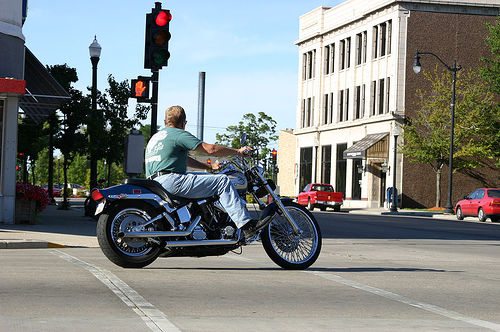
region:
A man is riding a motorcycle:
[30, 22, 485, 317]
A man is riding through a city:
[17, 36, 472, 308]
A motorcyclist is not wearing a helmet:
[25, 40, 455, 305]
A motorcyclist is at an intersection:
[21, 50, 481, 315]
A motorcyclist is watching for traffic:
[20, 26, 463, 322]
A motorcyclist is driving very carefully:
[2, 48, 474, 314]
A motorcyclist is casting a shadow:
[15, 25, 480, 316]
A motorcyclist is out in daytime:
[31, 16, 471, 321]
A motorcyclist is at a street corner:
[11, 51, 452, 328]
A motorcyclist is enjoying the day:
[40, 28, 447, 298]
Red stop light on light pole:
[138, 7, 183, 73]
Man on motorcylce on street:
[68, 105, 341, 270]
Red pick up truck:
[293, 178, 347, 210]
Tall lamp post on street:
[396, 42, 470, 209]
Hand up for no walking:
[123, 78, 150, 102]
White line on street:
[62, 266, 174, 330]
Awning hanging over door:
[336, 130, 397, 161]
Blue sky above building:
[215, 43, 288, 87]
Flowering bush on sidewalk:
[16, 178, 51, 225]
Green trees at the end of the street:
[236, 107, 273, 143]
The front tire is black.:
[265, 196, 321, 270]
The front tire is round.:
[258, 203, 323, 268]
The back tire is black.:
[96, 198, 168, 266]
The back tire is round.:
[96, 194, 167, 270]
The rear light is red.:
[91, 185, 102, 202]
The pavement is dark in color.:
[232, 277, 307, 320]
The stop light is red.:
[153, 6, 173, 30]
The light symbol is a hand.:
[131, 81, 152, 98]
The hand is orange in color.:
[132, 75, 147, 100]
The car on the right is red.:
[451, 188, 498, 218]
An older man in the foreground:
[72, 98, 335, 283]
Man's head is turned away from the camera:
[147, 102, 197, 131]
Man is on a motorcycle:
[74, 97, 334, 279]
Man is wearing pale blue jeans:
[153, 155, 263, 247]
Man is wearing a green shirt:
[137, 120, 203, 190]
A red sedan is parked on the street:
[448, 172, 499, 232]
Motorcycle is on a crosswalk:
[73, 100, 343, 281]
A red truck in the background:
[285, 174, 352, 219]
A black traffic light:
[130, 5, 185, 85]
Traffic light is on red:
[140, 7, 182, 75]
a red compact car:
[454, 188, 498, 220]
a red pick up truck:
[296, 184, 341, 210]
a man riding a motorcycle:
[82, 107, 322, 267]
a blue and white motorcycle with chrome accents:
[83, 145, 323, 269]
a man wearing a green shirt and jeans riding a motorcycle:
[144, 105, 272, 237]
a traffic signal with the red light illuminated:
[143, 3, 173, 69]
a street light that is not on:
[88, 35, 100, 185]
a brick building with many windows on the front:
[293, 0, 498, 207]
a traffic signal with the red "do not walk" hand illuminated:
[130, 78, 150, 99]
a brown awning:
[342, 133, 389, 165]